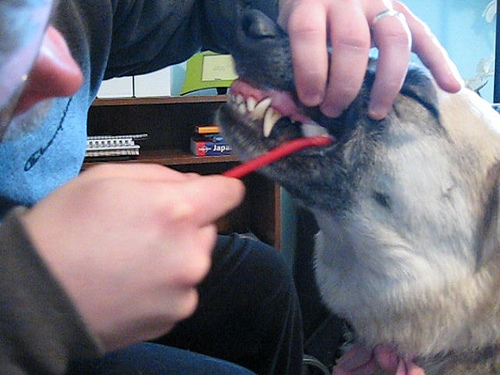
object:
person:
[1, 2, 465, 375]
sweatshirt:
[0, 1, 285, 374]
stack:
[189, 124, 235, 159]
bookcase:
[81, 94, 283, 252]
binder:
[81, 133, 147, 163]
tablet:
[79, 131, 149, 160]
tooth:
[245, 96, 257, 112]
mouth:
[211, 68, 347, 179]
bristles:
[301, 123, 327, 138]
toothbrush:
[217, 121, 335, 178]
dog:
[215, 6, 499, 375]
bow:
[333, 340, 425, 375]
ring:
[370, 9, 405, 32]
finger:
[364, 5, 417, 121]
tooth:
[261, 107, 281, 139]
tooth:
[249, 95, 274, 122]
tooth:
[235, 92, 242, 107]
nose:
[237, 6, 284, 41]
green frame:
[177, 48, 238, 100]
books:
[188, 139, 240, 158]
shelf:
[72, 136, 271, 175]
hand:
[21, 157, 249, 355]